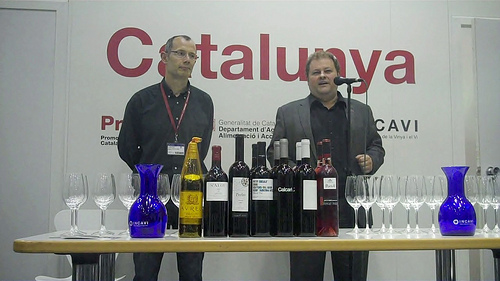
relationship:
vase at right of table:
[436, 162, 479, 237] [15, 225, 499, 249]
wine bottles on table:
[178, 133, 340, 236] [4, 226, 496, 253]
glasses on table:
[338, 172, 499, 236] [4, 226, 496, 253]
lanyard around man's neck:
[157, 83, 189, 160] [160, 70, 190, 92]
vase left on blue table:
[125, 161, 169, 238] [15, 225, 499, 249]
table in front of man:
[15, 225, 499, 249] [113, 32, 217, 279]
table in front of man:
[15, 225, 499, 249] [271, 55, 383, 278]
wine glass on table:
[345, 175, 367, 235] [10, 214, 498, 280]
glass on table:
[61, 171, 88, 238] [15, 225, 499, 249]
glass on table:
[91, 172, 121, 237] [15, 225, 499, 249]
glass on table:
[116, 170, 141, 237] [15, 225, 499, 249]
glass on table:
[344, 173, 367, 237] [15, 225, 499, 249]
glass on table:
[382, 175, 402, 235] [15, 225, 499, 249]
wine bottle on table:
[175, 134, 205, 235] [16, 227, 497, 272]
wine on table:
[201, 142, 231, 233] [15, 225, 499, 249]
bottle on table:
[315, 136, 344, 236] [15, 225, 499, 249]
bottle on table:
[296, 136, 317, 237] [15, 225, 499, 249]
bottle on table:
[273, 140, 297, 235] [15, 225, 499, 249]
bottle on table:
[230, 132, 250, 233] [15, 225, 499, 249]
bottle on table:
[176, 138, 204, 238] [15, 225, 499, 249]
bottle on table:
[322, 134, 338, 237] [11, 233, 498, 263]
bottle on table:
[297, 139, 318, 232] [11, 233, 498, 263]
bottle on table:
[277, 138, 296, 236] [11, 233, 498, 263]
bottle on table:
[252, 139, 272, 237] [11, 233, 498, 263]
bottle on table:
[229, 133, 251, 234] [11, 233, 498, 263]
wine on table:
[272, 136, 298, 236] [15, 225, 499, 249]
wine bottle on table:
[274, 138, 297, 235] [15, 225, 499, 249]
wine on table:
[174, 133, 206, 238] [8, 202, 485, 264]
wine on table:
[204, 134, 231, 241] [8, 202, 485, 264]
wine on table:
[230, 127, 254, 236] [8, 202, 485, 264]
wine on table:
[246, 128, 274, 241] [8, 202, 485, 264]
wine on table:
[313, 131, 344, 244] [8, 202, 485, 264]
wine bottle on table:
[316, 132, 339, 238] [13, 217, 485, 268]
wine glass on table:
[63, 171, 85, 240] [15, 225, 499, 249]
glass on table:
[59, 171, 91, 238] [7, 229, 495, 269]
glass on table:
[346, 172, 368, 221] [255, 222, 430, 254]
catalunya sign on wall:
[66, 2, 451, 174] [67, 0, 494, 277]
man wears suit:
[271, 55, 383, 278] [276, 93, 378, 278]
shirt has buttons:
[115, 71, 217, 193] [162, 90, 173, 100]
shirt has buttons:
[115, 71, 217, 193] [179, 94, 191, 101]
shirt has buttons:
[115, 71, 217, 193] [173, 97, 181, 107]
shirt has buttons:
[115, 71, 217, 193] [169, 115, 184, 123]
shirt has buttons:
[115, 71, 217, 193] [169, 161, 182, 171]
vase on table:
[436, 162, 479, 237] [12, 228, 498, 250]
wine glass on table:
[344, 176, 369, 231] [14, 229, 496, 253]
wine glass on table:
[354, 170, 381, 232] [14, 229, 496, 253]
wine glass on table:
[156, 170, 172, 202] [14, 229, 496, 253]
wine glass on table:
[475, 171, 494, 236] [14, 229, 496, 253]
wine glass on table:
[462, 173, 478, 202] [14, 229, 496, 253]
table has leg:
[15, 225, 499, 249] [68, 252, 103, 279]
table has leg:
[15, 225, 499, 249] [101, 253, 118, 279]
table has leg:
[15, 225, 499, 249] [434, 248, 454, 279]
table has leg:
[15, 225, 499, 249] [491, 248, 498, 278]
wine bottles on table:
[154, 135, 354, 235] [183, 130, 343, 240]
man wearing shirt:
[271, 55, 383, 278] [307, 96, 353, 176]